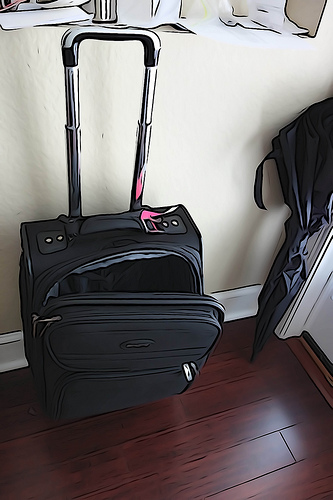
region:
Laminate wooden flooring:
[2, 296, 331, 498]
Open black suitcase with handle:
[13, 31, 216, 419]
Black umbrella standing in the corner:
[241, 63, 329, 392]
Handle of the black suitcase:
[48, 25, 166, 216]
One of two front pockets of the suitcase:
[45, 304, 221, 380]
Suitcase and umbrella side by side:
[3, 17, 327, 427]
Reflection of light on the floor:
[213, 387, 317, 499]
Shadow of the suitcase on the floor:
[19, 366, 230, 499]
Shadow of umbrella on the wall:
[228, 52, 325, 350]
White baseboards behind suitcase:
[0, 268, 273, 391]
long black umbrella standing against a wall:
[236, 48, 330, 369]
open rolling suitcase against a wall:
[18, 20, 223, 429]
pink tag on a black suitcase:
[135, 206, 186, 235]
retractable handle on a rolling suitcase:
[48, 21, 167, 216]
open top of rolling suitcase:
[38, 238, 227, 340]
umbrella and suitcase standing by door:
[21, 24, 331, 435]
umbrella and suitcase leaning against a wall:
[18, 26, 325, 428]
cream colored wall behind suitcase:
[2, 28, 319, 331]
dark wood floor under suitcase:
[3, 306, 331, 497]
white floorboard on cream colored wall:
[2, 276, 295, 376]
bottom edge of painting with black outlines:
[1, 0, 330, 38]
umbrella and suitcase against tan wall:
[0, 1, 332, 328]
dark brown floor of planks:
[2, 311, 326, 493]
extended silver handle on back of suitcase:
[51, 15, 153, 199]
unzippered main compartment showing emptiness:
[18, 235, 211, 327]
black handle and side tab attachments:
[28, 210, 185, 249]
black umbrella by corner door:
[244, 79, 323, 364]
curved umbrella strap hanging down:
[249, 146, 283, 209]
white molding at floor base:
[0, 279, 259, 371]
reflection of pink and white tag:
[129, 159, 180, 232]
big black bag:
[14, 27, 220, 427]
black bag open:
[17, 204, 220, 429]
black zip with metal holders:
[43, 358, 207, 387]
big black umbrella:
[246, 87, 331, 376]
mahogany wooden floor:
[1, 302, 328, 498]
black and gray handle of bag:
[61, 16, 157, 213]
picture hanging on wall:
[0, 2, 327, 32]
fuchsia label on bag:
[137, 203, 162, 230]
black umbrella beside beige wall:
[250, 98, 330, 370]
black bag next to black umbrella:
[18, 17, 220, 423]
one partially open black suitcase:
[20, 203, 226, 418]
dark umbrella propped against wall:
[243, 70, 331, 367]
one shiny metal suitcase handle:
[58, 21, 162, 215]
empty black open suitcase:
[23, 219, 222, 421]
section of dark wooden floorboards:
[31, 427, 325, 498]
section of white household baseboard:
[225, 282, 255, 321]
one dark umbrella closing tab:
[250, 148, 275, 213]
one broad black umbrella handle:
[70, 212, 145, 238]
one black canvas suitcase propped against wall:
[10, 22, 232, 414]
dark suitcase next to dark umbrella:
[13, 24, 331, 412]